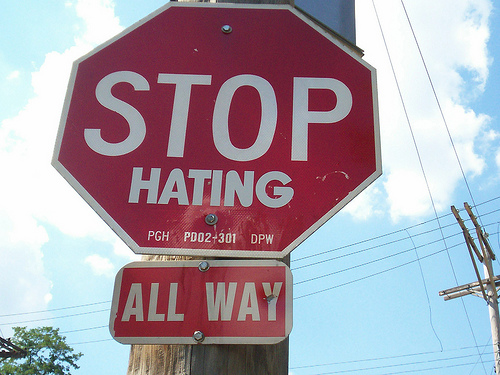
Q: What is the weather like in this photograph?
A: It is clear.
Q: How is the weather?
A: It is clear.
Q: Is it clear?
A: Yes, it is clear.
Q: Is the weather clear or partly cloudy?
A: It is clear.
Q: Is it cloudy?
A: No, it is clear.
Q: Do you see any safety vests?
A: No, there are no safety vests.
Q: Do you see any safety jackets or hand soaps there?
A: No, there are no safety jackets or hand soaps.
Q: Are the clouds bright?
A: Yes, the clouds are bright.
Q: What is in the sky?
A: The clouds are in the sky.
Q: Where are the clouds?
A: The clouds are in the sky.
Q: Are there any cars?
A: No, there are no cars.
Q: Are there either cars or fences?
A: No, there are no cars or fences.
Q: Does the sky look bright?
A: Yes, the sky is bright.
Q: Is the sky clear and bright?
A: Yes, the sky is clear and bright.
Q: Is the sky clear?
A: Yes, the sky is clear.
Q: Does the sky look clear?
A: Yes, the sky is clear.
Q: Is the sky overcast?
A: No, the sky is clear.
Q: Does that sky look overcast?
A: No, the sky is clear.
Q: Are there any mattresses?
A: No, there are no mattresses.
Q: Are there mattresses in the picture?
A: No, there are no mattresses.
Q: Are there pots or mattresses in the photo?
A: No, there are no mattresses or pots.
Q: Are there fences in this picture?
A: No, there are no fences.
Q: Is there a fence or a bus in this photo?
A: No, there are no fences or buses.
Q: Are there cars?
A: No, there are no cars.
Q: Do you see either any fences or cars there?
A: No, there are no cars or fences.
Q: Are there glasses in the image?
A: No, there are no glasses.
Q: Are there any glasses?
A: No, there are no glasses.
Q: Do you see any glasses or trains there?
A: No, there are no glasses or trains.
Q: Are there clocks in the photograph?
A: No, there are no clocks.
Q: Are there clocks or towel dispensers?
A: No, there are no clocks or towel dispensers.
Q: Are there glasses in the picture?
A: No, there are no glasses.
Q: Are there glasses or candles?
A: No, there are no glasses or candles.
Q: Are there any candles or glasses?
A: No, there are no glasses or candles.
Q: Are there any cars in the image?
A: No, there are no cars.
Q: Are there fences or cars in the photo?
A: No, there are no cars or fences.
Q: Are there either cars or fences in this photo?
A: No, there are no cars or fences.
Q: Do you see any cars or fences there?
A: No, there are no cars or fences.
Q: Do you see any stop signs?
A: Yes, there is a stop sign.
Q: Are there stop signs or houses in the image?
A: Yes, there is a stop sign.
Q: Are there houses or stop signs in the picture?
A: Yes, there is a stop sign.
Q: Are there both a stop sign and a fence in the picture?
A: No, there is a stop sign but no fences.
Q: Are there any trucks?
A: No, there are no trucks.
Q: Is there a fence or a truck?
A: No, there are no trucks or fences.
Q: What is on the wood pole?
A: The stop sign is on the pole.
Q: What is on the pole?
A: The stop sign is on the pole.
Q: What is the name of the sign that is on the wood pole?
A: The sign is a stop sign.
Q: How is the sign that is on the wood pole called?
A: The sign is a stop sign.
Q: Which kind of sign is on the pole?
A: The sign is a stop sign.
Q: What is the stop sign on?
A: The stop sign is on the pole.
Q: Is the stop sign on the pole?
A: Yes, the stop sign is on the pole.